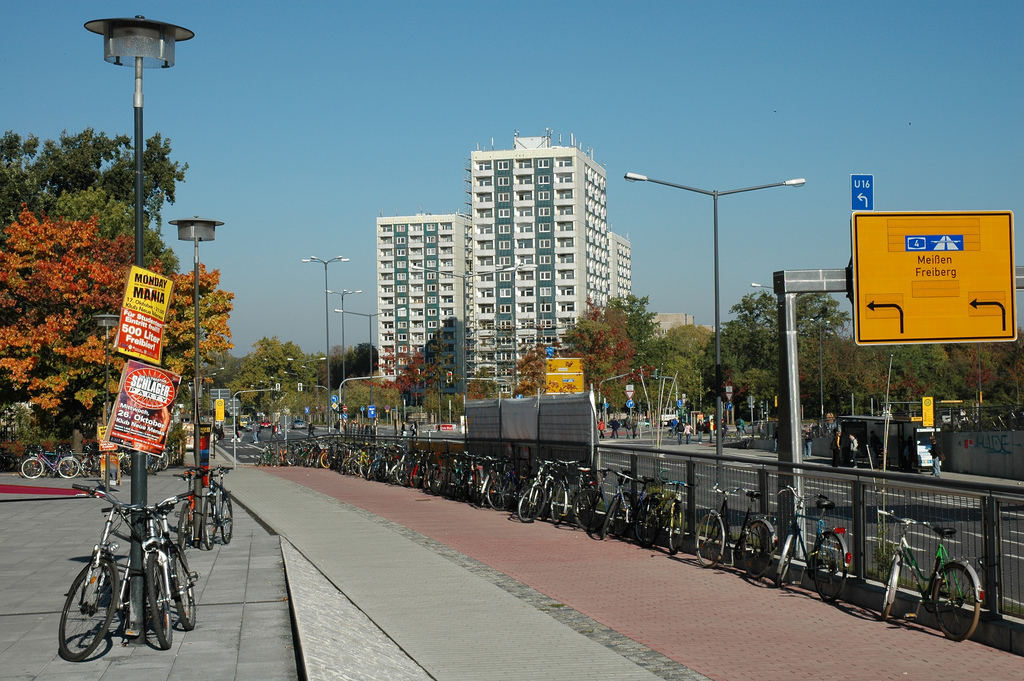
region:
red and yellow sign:
[115, 265, 169, 358]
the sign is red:
[111, 352, 179, 454]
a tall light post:
[77, 11, 194, 623]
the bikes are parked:
[57, 483, 198, 660]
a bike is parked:
[17, 450, 76, 480]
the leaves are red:
[1, 204, 233, 419]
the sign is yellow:
[846, 210, 1015, 346]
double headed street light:
[623, 167, 805, 449]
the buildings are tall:
[375, 131, 626, 384]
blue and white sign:
[851, 173, 874, 213]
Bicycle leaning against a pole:
[114, 487, 217, 647]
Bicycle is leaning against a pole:
[103, 481, 228, 652]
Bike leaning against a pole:
[124, 484, 219, 649]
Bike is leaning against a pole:
[106, 485, 231, 653]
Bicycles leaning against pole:
[43, 465, 217, 653]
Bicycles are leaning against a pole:
[45, 465, 205, 665]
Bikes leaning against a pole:
[46, 463, 217, 667]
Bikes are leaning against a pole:
[40, 456, 218, 668]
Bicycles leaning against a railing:
[264, 411, 985, 658]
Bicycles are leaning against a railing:
[256, 428, 991, 660]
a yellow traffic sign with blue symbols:
[840, 194, 1022, 372]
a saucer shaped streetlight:
[65, 9, 199, 652]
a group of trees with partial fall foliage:
[2, 118, 240, 489]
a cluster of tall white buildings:
[365, 119, 642, 413]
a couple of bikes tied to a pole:
[39, 476, 211, 676]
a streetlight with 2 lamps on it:
[621, 154, 821, 445]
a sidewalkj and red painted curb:
[1, 470, 106, 510]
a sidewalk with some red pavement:
[197, 457, 1017, 679]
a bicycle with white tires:
[15, 441, 88, 489]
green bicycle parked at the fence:
[872, 506, 987, 643]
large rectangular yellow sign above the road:
[852, 208, 1020, 346]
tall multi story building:
[467, 127, 613, 394]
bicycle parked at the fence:
[773, 481, 856, 606]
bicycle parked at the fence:
[691, 483, 781, 585]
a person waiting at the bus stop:
[844, 430, 863, 472]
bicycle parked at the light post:
[126, 490, 202, 650]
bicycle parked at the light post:
[54, 481, 141, 660]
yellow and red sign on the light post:
[110, 260, 177, 366]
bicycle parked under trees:
[19, 439, 81, 479]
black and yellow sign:
[853, 205, 1012, 355]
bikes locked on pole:
[54, 458, 229, 661]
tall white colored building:
[462, 111, 618, 321]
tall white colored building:
[379, 217, 468, 326]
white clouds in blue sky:
[291, 224, 331, 276]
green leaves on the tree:
[910, 371, 950, 391]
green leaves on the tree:
[721, 331, 770, 377]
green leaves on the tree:
[607, 296, 621, 319]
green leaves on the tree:
[594, 334, 629, 376]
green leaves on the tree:
[399, 378, 438, 408]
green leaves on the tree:
[257, 337, 297, 377]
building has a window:
[473, 156, 494, 177]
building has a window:
[438, 221, 451, 231]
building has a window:
[423, 221, 437, 231]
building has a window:
[410, 221, 423, 229]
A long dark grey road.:
[217, 425, 1023, 612]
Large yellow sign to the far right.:
[843, 203, 1014, 355]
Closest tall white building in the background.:
[468, 126, 612, 380]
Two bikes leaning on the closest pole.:
[53, 481, 202, 659]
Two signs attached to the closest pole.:
[101, 259, 184, 465]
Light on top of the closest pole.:
[76, 7, 197, 78]